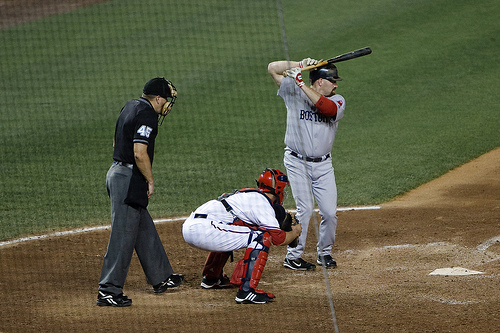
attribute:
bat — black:
[300, 46, 372, 71]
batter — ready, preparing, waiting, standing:
[268, 57, 343, 272]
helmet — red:
[256, 168, 289, 206]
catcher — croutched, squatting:
[181, 162, 303, 296]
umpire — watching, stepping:
[96, 77, 185, 296]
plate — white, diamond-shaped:
[430, 267, 486, 276]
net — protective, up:
[0, 0, 342, 333]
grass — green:
[284, 0, 498, 205]